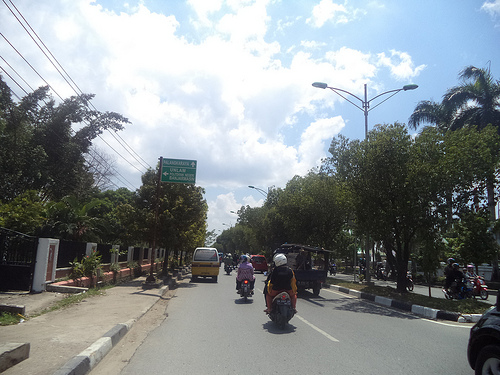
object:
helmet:
[272, 254, 288, 268]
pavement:
[0, 263, 175, 374]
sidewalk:
[327, 271, 500, 326]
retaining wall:
[34, 239, 186, 294]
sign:
[160, 157, 196, 184]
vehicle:
[190, 247, 222, 284]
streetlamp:
[311, 82, 420, 282]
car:
[251, 254, 268, 274]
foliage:
[407, 63, 499, 132]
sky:
[3, 1, 500, 247]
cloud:
[382, 50, 424, 82]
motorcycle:
[263, 276, 295, 330]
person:
[452, 262, 463, 288]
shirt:
[446, 268, 463, 284]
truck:
[275, 244, 331, 298]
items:
[288, 250, 321, 272]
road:
[88, 260, 500, 375]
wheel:
[480, 358, 500, 375]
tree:
[328, 123, 434, 293]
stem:
[395, 233, 404, 261]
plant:
[68, 258, 87, 280]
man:
[265, 253, 298, 310]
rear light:
[244, 279, 250, 285]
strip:
[293, 311, 339, 344]